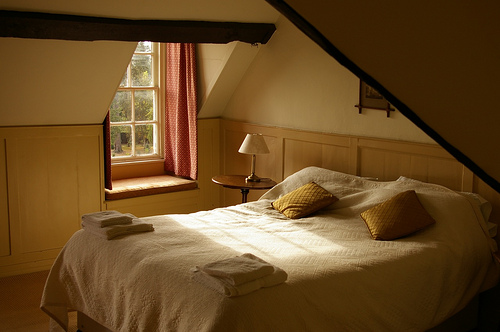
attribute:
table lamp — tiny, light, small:
[238, 134, 269, 182]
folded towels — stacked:
[190, 254, 289, 298]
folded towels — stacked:
[82, 210, 154, 240]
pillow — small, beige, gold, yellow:
[358, 190, 435, 243]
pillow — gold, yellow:
[271, 181, 338, 218]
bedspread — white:
[40, 166, 500, 330]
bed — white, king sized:
[40, 167, 500, 331]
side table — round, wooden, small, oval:
[211, 174, 277, 204]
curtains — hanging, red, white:
[104, 43, 198, 190]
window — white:
[109, 41, 167, 165]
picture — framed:
[353, 77, 396, 118]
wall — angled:
[220, 14, 499, 262]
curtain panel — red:
[165, 44, 199, 181]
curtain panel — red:
[103, 109, 112, 190]